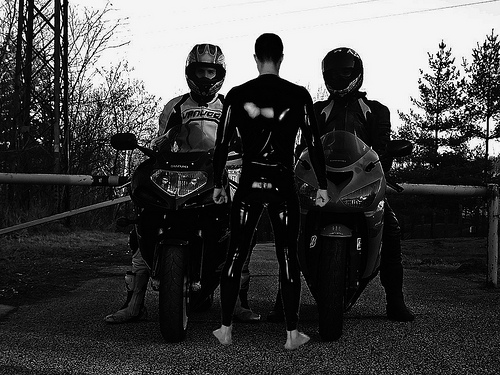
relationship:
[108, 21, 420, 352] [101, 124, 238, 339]
people on motorcycle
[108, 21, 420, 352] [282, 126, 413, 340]
people on motorcycle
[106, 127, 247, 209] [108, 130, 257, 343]
lights on bike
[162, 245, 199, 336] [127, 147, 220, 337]
tire on bike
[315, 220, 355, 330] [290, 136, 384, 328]
tire on bike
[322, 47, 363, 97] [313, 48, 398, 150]
helmet on man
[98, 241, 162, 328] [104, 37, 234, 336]
boots on rider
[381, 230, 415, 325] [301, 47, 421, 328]
boots on rider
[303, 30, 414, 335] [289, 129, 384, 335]
person on motorcycle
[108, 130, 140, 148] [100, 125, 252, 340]
mirror on motorcycle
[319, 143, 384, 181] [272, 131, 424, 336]
windshield on motorcycle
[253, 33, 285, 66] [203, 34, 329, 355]
head on man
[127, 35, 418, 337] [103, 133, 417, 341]
two men on bikes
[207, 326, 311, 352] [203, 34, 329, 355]
bare feet on man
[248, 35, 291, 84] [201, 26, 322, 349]
head of person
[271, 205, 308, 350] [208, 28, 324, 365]
leg of person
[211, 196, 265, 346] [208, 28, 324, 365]
leg of person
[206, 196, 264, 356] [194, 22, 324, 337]
leg of person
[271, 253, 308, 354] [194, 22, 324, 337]
leg of person